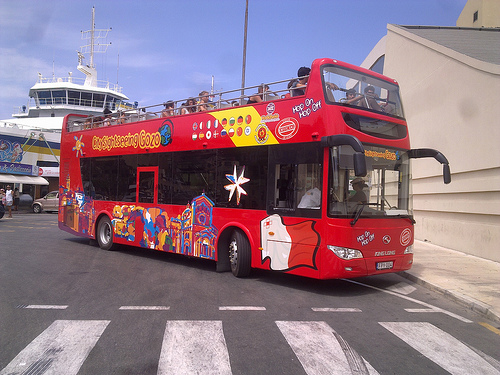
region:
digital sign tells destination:
[360, 150, 398, 161]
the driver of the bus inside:
[346, 175, 374, 206]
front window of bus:
[323, 149, 415, 221]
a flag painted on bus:
[256, 215, 328, 272]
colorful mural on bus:
[138, 198, 221, 258]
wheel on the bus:
[220, 223, 253, 275]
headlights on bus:
[324, 245, 364, 260]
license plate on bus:
[374, 257, 397, 272]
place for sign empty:
[350, 118, 406, 138]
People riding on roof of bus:
[61, 63, 396, 132]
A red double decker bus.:
[56, 57, 416, 280]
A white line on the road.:
[159, 318, 233, 374]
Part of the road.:
[55, 268, 115, 286]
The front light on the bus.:
[326, 242, 363, 262]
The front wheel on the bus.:
[226, 229, 248, 275]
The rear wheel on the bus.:
[94, 216, 114, 247]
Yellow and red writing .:
[91, 131, 160, 148]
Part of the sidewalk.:
[436, 258, 462, 282]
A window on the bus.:
[171, 151, 214, 206]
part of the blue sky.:
[141, 18, 190, 50]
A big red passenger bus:
[51, 79, 438, 300]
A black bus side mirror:
[331, 134, 373, 176]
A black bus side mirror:
[405, 149, 456, 181]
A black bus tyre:
[220, 225, 245, 275]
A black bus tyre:
[97, 216, 119, 259]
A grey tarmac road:
[15, 224, 71, 291]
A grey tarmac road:
[72, 219, 167, 315]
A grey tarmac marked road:
[63, 244, 179, 372]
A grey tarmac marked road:
[206, 284, 311, 369]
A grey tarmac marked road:
[325, 275, 425, 367]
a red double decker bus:
[38, 50, 467, 286]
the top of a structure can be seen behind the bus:
[9, 4, 157, 124]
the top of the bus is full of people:
[58, 63, 415, 133]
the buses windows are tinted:
[73, 146, 264, 208]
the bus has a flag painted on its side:
[246, 210, 321, 270]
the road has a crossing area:
[6, 296, 497, 373]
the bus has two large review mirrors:
[328, 137, 460, 185]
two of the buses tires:
[87, 207, 256, 279]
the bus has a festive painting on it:
[53, 155, 222, 268]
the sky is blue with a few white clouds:
[31, 5, 438, 75]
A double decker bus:
[55, 55, 419, 287]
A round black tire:
[221, 224, 255, 282]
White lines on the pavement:
[2, 277, 498, 373]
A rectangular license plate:
[372, 257, 396, 273]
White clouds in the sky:
[1, 0, 240, 119]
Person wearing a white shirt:
[1, 182, 17, 204]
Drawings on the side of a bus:
[59, 169, 253, 261]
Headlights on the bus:
[327, 235, 417, 263]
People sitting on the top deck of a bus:
[81, 64, 382, 133]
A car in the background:
[27, 184, 67, 218]